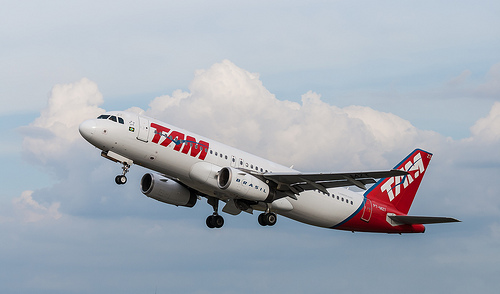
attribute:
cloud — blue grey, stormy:
[1, 64, 498, 225]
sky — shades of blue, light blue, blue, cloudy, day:
[0, 1, 499, 292]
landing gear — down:
[115, 166, 277, 230]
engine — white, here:
[216, 167, 277, 204]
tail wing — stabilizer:
[388, 216, 460, 225]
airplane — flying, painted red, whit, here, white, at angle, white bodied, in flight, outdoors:
[78, 111, 460, 235]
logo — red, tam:
[149, 123, 211, 161]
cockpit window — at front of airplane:
[97, 114, 124, 124]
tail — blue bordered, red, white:
[364, 148, 434, 214]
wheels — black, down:
[114, 174, 124, 185]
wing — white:
[253, 170, 407, 201]